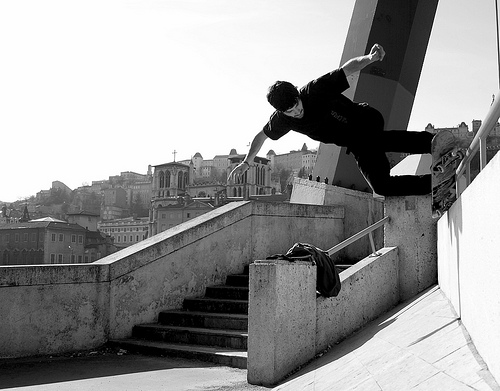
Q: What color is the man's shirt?
A: Black.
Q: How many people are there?
A: 1.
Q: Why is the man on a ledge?
A: Showcase.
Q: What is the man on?
A: Skateboard.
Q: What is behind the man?
A: City.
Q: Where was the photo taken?
A: Along a building.